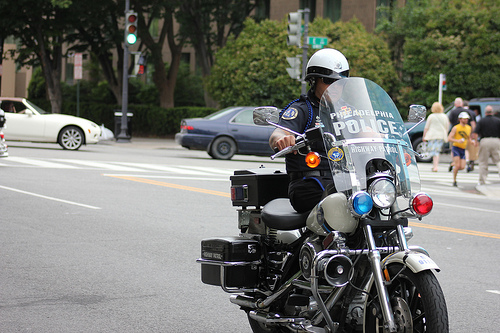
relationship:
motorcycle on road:
[184, 75, 451, 331] [4, 147, 500, 332]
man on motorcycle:
[268, 47, 354, 307] [184, 75, 451, 331]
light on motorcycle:
[303, 149, 321, 169] [184, 75, 451, 331]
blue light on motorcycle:
[351, 192, 373, 216] [184, 75, 451, 331]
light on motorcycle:
[370, 177, 399, 211] [258, 88, 445, 245]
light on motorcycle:
[410, 192, 434, 217] [184, 75, 451, 331]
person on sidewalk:
[445, 111, 476, 187] [408, 164, 498, 203]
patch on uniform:
[276, 103, 299, 127] [286, 100, 316, 193]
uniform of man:
[286, 100, 316, 193] [271, 29, 368, 286]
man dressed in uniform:
[258, 34, 386, 266] [278, 100, 338, 216]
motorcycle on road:
[184, 75, 451, 331] [4, 148, 494, 330]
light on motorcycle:
[410, 192, 434, 217] [195, 75, 451, 333]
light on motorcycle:
[367, 177, 398, 211] [195, 75, 451, 333]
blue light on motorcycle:
[351, 192, 375, 216] [195, 75, 451, 333]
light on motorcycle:
[306, 152, 318, 163] [195, 75, 451, 333]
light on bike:
[410, 192, 434, 217] [196, 48, 448, 330]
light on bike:
[367, 177, 398, 211] [190, 122, 453, 328]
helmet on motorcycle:
[303, 48, 349, 81] [195, 75, 451, 333]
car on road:
[0, 96, 121, 147] [4, 148, 494, 330]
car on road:
[174, 102, 284, 162] [4, 148, 494, 330]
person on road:
[445, 111, 476, 187] [4, 148, 494, 330]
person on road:
[422, 100, 455, 180] [13, 141, 179, 326]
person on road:
[474, 105, 499, 188] [412, 155, 499, 209]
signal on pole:
[284, 10, 300, 46] [299, 6, 310, 88]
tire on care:
[212, 135, 234, 158] [177, 85, 299, 177]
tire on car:
[49, 124, 99, 158] [0, 92, 114, 151]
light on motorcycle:
[410, 191, 437, 213] [195, 75, 451, 333]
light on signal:
[125, 31, 145, 47] [110, 4, 148, 141]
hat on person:
[461, 113, 467, 119] [447, 112, 469, 188]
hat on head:
[461, 113, 467, 119] [459, 114, 469, 120]